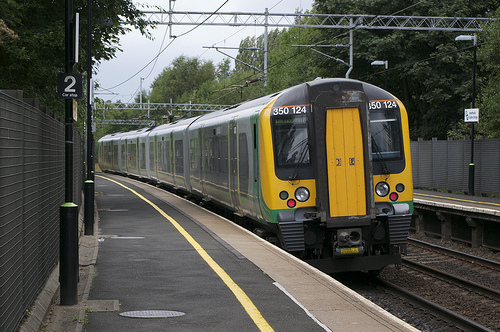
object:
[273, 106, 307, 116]
number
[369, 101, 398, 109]
number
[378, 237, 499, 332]
track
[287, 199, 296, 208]
front light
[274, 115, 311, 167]
window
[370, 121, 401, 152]
window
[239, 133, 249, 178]
window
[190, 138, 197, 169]
window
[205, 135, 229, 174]
window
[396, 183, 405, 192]
front light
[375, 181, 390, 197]
front light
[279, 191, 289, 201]
front light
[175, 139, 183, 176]
window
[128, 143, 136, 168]
window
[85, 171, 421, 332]
platform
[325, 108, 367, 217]
door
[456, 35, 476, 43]
light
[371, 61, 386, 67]
light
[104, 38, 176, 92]
wires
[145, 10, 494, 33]
poles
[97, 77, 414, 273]
passenger train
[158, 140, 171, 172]
window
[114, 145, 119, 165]
window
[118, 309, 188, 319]
cover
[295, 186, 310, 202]
front light